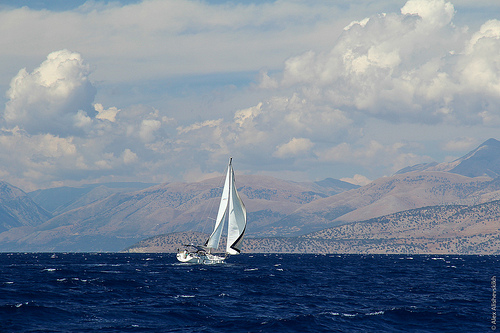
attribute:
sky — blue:
[1, 1, 498, 190]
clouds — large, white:
[6, 1, 498, 185]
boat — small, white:
[173, 155, 250, 270]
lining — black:
[193, 173, 330, 267]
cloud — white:
[353, 41, 415, 103]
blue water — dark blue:
[11, 252, 498, 329]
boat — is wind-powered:
[149, 135, 273, 308]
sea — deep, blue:
[24, 237, 411, 332]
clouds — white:
[245, 8, 498, 149]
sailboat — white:
[168, 157, 256, 276]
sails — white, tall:
[204, 152, 251, 257]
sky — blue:
[186, 47, 264, 121]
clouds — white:
[347, 47, 405, 104]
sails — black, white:
[181, 154, 247, 254]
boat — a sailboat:
[164, 166, 260, 265]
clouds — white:
[315, 53, 451, 124]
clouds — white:
[170, 95, 291, 162]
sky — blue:
[17, 10, 497, 154]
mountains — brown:
[327, 164, 441, 251]